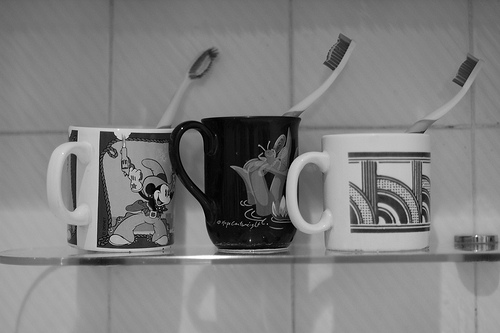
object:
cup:
[169, 115, 301, 254]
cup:
[48, 125, 177, 257]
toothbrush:
[408, 51, 482, 135]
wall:
[2, 0, 500, 332]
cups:
[286, 131, 431, 257]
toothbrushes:
[281, 33, 358, 119]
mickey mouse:
[109, 130, 177, 247]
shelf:
[1, 245, 500, 264]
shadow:
[181, 259, 308, 333]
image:
[350, 154, 431, 230]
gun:
[119, 129, 132, 177]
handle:
[284, 150, 332, 234]